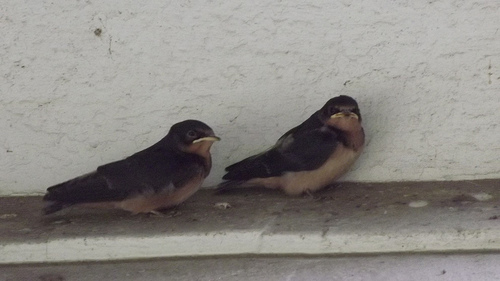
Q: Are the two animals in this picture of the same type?
A: Yes, all the animals are birds.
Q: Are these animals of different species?
A: No, all the animals are birds.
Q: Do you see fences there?
A: No, there are no fences.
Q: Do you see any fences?
A: No, there are no fences.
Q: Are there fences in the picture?
A: No, there are no fences.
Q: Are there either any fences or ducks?
A: No, there are no fences or ducks.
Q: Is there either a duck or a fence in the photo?
A: No, there are no fences or ducks.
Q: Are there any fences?
A: No, there are no fences.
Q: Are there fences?
A: No, there are no fences.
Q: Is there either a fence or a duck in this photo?
A: No, there are no fences or ducks.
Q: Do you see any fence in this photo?
A: No, there are no fences.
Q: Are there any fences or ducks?
A: No, there are no fences or ducks.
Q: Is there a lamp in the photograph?
A: No, there are no lamps.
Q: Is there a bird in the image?
A: Yes, there is a bird.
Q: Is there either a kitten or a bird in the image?
A: Yes, there is a bird.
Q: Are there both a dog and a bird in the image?
A: No, there is a bird but no dogs.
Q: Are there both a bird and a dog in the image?
A: No, there is a bird but no dogs.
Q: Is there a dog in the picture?
A: No, there are no dogs.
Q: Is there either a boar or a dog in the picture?
A: No, there are no dogs or boars.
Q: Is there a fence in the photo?
A: No, there are no fences.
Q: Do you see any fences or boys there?
A: No, there are no fences or boys.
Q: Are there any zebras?
A: No, there are no zebras.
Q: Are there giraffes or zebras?
A: No, there are no zebras or giraffes.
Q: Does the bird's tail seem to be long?
A: Yes, the tail is long.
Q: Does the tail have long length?
A: Yes, the tail is long.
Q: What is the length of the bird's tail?
A: The tail is long.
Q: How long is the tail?
A: The tail is long.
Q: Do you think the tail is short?
A: No, the tail is long.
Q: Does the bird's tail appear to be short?
A: No, the tail is long.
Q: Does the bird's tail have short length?
A: No, the tail is long.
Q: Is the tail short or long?
A: The tail is long.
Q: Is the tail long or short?
A: The tail is long.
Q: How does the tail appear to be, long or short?
A: The tail is long.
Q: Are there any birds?
A: Yes, there is a bird.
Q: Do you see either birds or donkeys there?
A: Yes, there is a bird.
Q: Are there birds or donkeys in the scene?
A: Yes, there is a bird.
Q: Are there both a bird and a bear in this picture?
A: No, there is a bird but no bears.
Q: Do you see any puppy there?
A: No, there are no puppys.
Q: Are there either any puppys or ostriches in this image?
A: No, there are no puppys or ostriches.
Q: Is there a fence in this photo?
A: No, there are no fences.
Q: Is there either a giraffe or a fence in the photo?
A: No, there are no fences or giraffes.